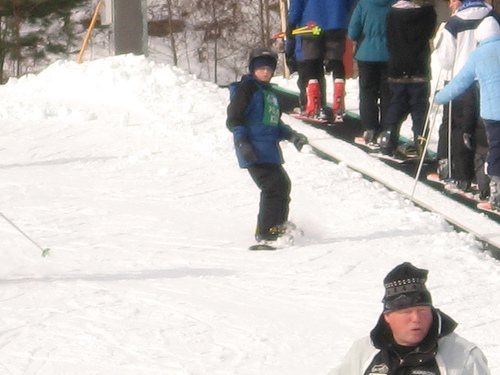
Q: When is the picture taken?
A: Daytime.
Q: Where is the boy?
A: On a slope.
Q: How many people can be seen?
A: 7.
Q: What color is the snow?
A: White.